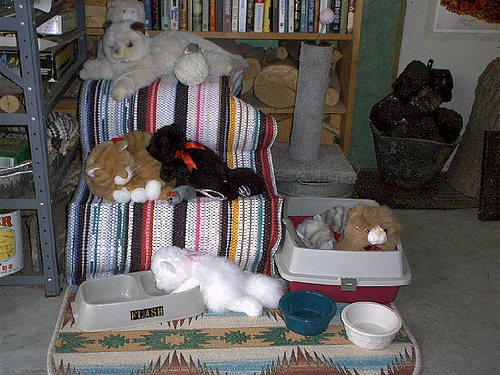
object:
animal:
[338, 201, 402, 255]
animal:
[75, 20, 249, 100]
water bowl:
[277, 288, 336, 333]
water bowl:
[341, 298, 404, 351]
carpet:
[289, 41, 334, 167]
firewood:
[267, 109, 347, 147]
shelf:
[246, 105, 345, 117]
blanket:
[63, 77, 282, 285]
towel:
[43, 329, 421, 373]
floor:
[8, 285, 495, 375]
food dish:
[71, 269, 210, 331]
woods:
[129, 304, 165, 321]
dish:
[70, 269, 207, 334]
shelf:
[0, 0, 64, 295]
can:
[0, 205, 26, 282]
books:
[150, 1, 357, 37]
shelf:
[154, 26, 360, 40]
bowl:
[277, 285, 338, 338]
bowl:
[340, 299, 404, 352]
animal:
[151, 240, 287, 317]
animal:
[144, 124, 265, 201]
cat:
[78, 129, 168, 202]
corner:
[18, 106, 47, 128]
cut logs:
[245, 60, 302, 112]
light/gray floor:
[12, 274, 500, 369]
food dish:
[339, 296, 403, 349]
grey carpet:
[271, 141, 359, 188]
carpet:
[0, 182, 499, 375]